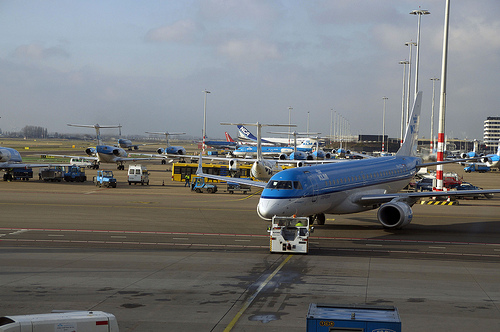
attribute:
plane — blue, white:
[255, 142, 433, 231]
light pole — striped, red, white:
[440, 9, 464, 174]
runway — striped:
[95, 210, 183, 242]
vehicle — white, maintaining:
[267, 211, 312, 256]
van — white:
[132, 164, 152, 183]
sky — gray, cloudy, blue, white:
[144, 28, 157, 43]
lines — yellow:
[54, 187, 107, 225]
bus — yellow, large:
[176, 164, 258, 209]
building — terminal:
[342, 137, 394, 160]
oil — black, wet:
[241, 260, 297, 317]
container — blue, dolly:
[303, 303, 392, 331]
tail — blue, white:
[395, 104, 432, 178]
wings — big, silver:
[387, 188, 495, 196]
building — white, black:
[485, 114, 500, 150]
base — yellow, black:
[419, 198, 454, 216]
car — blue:
[94, 170, 126, 193]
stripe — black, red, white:
[324, 185, 363, 199]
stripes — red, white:
[38, 223, 42, 228]